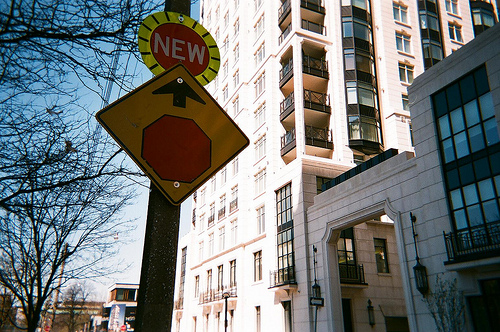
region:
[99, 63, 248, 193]
a sign is on a pole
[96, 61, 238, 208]
a sign is on the street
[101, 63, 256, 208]
the street sign is diamond shaped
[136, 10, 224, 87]
a sign is above the sign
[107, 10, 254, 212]
two sign are on a pole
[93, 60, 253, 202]
the sign is yellow in color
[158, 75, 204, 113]
an arrow is on the sign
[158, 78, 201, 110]
the arrow is black in color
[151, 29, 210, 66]
lettering is on the sign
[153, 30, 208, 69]
the lettering is white in color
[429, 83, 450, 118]
The window is rectangular.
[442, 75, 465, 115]
The window is rectangular.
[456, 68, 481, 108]
The window is rectangular.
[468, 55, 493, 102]
The window is rectangular.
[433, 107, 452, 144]
The window is rectangular.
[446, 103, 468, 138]
The window is rectangular.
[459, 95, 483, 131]
The window is rectangular.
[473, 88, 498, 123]
The window is rectangular.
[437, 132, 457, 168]
The window is rectangular.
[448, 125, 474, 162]
The window is rectangular.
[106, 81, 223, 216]
red and yellow sign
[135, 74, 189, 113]
black arrow points forward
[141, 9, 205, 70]
red and yellow sign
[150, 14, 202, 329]
two signs on pole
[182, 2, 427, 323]
tall and white building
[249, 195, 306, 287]
black windows on building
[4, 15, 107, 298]
bare trees behind signs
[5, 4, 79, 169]
blue and clear sky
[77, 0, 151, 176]
power lines behind trees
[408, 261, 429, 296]
the light is off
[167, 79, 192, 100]
the arrow is black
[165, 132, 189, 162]
the sign is red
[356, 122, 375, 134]
the curtains are closed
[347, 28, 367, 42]
the curtain is open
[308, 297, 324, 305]
the arrow is white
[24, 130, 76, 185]
the tree has no leaves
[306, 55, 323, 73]
the balcony is black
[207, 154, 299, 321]
A tall brown building's wall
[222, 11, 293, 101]
A tall brown building's wall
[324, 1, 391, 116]
A tall brown building's wall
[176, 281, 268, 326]
A tall brown building's wall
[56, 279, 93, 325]
A tall tree on the street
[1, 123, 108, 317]
A tall tree on the street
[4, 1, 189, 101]
A tall tree on the street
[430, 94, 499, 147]
A clear glass wall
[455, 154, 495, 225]
A clear glass wall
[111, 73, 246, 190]
A yellow shaped diamond sign.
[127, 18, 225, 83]
A sign on the pole.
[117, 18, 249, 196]
Two signs on the pole.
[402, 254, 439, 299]
Light on the wall.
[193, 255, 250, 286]
Windows on the building.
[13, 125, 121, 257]
The tree has no leaves.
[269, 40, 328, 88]
The balcony of the building.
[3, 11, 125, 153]
The sky is clear and blue.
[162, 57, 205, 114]
A black arrow on the sign.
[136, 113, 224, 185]
A red stop sign on yellow sign.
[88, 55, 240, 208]
a sign that is yellow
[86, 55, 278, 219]
a sign that is diamond shaped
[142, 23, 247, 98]
a sign that is circular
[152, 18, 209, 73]
a sign that is red